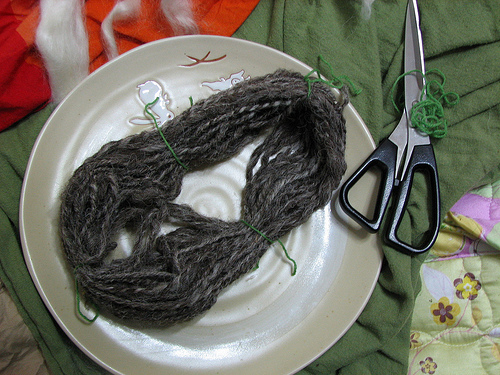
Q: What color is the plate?
A: Silver.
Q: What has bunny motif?
A: The white plate.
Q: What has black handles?
A: The shears.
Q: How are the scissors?
A: The have silver blades.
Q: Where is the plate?
A: On top of green flannel.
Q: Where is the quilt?
A: Under the flannel.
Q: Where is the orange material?
A: Under the plate.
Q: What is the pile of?
A: Gray yarn.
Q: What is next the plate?
A: Black and white scissors.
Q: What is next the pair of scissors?
A: A yellow and purple quilt.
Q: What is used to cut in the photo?
A: A scissor.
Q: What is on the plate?
A: Grey yarn.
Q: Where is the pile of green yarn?
A: By scissor.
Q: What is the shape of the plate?
A: Circle.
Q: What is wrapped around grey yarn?
A: Green string.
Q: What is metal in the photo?
A: Scissor.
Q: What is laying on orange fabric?
A: Cotton.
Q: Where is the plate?
A: On the blanket.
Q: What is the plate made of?
A: Porcelain.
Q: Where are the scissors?
A: Next to the plate.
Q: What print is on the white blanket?
A: Floral print.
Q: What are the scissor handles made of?
A: Plastic.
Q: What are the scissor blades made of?
A: Metal.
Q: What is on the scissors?
A: Green yarn.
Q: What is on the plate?
A: Gray yarn.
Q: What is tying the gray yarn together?
A: Green string.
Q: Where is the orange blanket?
A: Next to the green blanket.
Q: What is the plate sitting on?
A: A blanket.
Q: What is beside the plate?
A: Scissors.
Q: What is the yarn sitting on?
A: A plate.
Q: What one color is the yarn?
A: Grey.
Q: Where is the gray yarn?
A: On a plate.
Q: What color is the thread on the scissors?
A: Green.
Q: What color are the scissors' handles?
A: Black.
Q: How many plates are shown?
A: One.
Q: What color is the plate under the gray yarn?
A: White.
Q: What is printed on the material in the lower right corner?
A: Flowers.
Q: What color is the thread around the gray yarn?
A: Green.